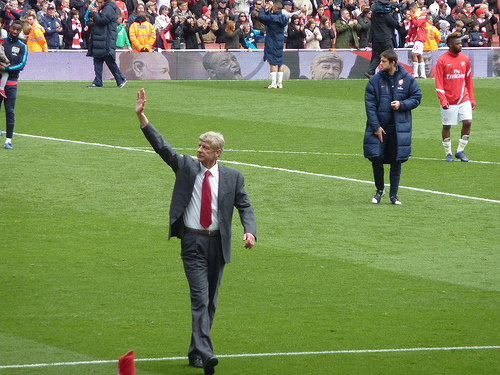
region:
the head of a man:
[191, 127, 226, 162]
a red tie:
[198, 170, 211, 230]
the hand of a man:
[240, 229, 259, 250]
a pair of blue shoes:
[446, 150, 467, 164]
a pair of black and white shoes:
[365, 188, 402, 205]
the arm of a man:
[134, 111, 181, 170]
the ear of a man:
[212, 147, 223, 158]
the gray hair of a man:
[196, 129, 224, 152]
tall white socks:
[268, 71, 283, 85]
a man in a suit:
[133, 86, 259, 373]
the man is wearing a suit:
[110, 72, 300, 369]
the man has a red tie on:
[184, 158, 229, 240]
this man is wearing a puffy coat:
[341, 37, 432, 219]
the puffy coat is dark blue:
[356, 42, 423, 202]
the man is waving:
[105, 72, 277, 369]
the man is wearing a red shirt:
[419, 18, 499, 170]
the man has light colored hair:
[183, 119, 235, 172]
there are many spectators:
[13, 1, 477, 47]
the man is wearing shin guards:
[435, 112, 476, 169]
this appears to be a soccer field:
[10, 82, 483, 372]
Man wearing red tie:
[191, 160, 226, 230]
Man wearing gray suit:
[121, 116, 252, 336]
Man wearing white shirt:
[172, 160, 218, 240]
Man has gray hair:
[193, 114, 254, 192]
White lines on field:
[279, 341, 428, 356]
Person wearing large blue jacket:
[338, 58, 427, 163]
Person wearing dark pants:
[356, 140, 388, 210]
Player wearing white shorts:
[423, 99, 481, 182]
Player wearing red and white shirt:
[423, 63, 495, 134]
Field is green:
[35, 92, 382, 314]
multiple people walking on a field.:
[6, 0, 487, 351]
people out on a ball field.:
[7, 26, 489, 358]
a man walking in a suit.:
[105, 75, 274, 371]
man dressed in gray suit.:
[114, 86, 258, 367]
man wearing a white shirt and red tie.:
[174, 125, 238, 222]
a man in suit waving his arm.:
[131, 70, 258, 367]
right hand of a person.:
[117, 82, 159, 139]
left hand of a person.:
[238, 224, 260, 272]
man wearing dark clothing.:
[355, 46, 430, 210]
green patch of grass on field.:
[275, 210, 464, 355]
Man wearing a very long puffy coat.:
[350, 40, 424, 214]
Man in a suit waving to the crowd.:
[127, 81, 265, 372]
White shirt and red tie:
[182, 162, 239, 229]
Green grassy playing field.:
[249, 222, 446, 367]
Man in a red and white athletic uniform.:
[432, 19, 483, 172]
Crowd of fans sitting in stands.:
[123, 0, 255, 45]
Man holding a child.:
[0, 15, 36, 160]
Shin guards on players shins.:
[437, 134, 477, 156]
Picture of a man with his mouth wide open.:
[195, 46, 245, 89]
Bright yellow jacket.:
[123, 18, 167, 60]